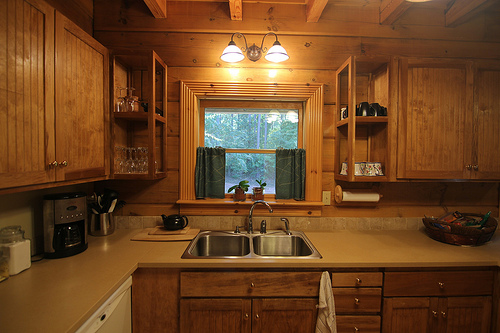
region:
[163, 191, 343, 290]
sink is silver and polished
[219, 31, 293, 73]
overhead lights in a kitchen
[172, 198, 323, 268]
stainless steel sink in a kitchen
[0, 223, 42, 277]
clear glass jar of flour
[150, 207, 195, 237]
black teapot on counter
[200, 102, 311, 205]
window above sink in kitchen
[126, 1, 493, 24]
wooden beams on ceiling in kitchen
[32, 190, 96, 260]
black and silver coffee maker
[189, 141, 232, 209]
green curtain on rod in window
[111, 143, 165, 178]
clear glasses upside down on shelf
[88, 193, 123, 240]
metal container of cooking utensils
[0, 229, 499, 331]
Entire light brown counter top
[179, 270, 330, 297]
Drawer just below the sink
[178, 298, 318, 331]
Two cupboards below the sink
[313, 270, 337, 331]
Dish towel hanging below the sink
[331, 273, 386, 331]
Stack of three drawers to the right of the sink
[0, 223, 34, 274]
Canister filled with white baking ingredient on the counter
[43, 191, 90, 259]
Coffeemaker on the counter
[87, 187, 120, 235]
Jar holding multiple utensils in the corner of the counter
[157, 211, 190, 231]
Black tea pot on the counter to the left of the sink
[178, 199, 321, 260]
Silver two-sided sink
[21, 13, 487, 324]
Picture of a kitchen.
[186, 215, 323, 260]
A stainles steel sink.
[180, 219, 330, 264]
A double kitchen sink.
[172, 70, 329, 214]
A small kitchen window.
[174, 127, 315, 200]
Curtains on bottom half of window.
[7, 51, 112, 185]
Wood cabinets on the left.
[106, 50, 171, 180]
Open shelves holding glasses.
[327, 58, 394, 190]
Open shelves holding cups.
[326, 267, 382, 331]
Small row of wooden drawers.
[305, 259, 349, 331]
Kitchen towel hanging on cabinet.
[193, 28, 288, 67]
these are lights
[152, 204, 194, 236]
this is a kettle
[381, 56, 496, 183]
this is side board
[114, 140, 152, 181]
these are wine glasses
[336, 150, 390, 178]
these are cups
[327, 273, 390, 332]
these are draws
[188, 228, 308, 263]
this is a sink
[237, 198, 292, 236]
this is a tap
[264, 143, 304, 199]
this is towel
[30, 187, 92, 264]
this is coffee maker